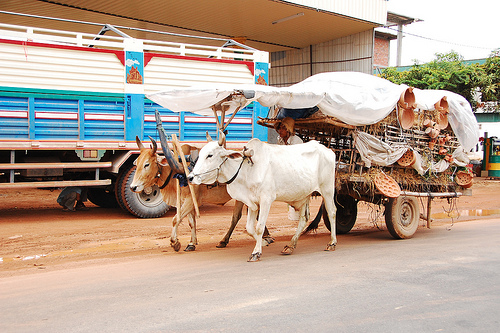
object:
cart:
[131, 70, 480, 262]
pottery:
[402, 86, 415, 128]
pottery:
[434, 97, 447, 126]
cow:
[187, 129, 339, 261]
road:
[218, 270, 498, 332]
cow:
[129, 134, 275, 249]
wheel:
[386, 191, 424, 239]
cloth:
[241, 71, 487, 141]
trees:
[398, 49, 496, 96]